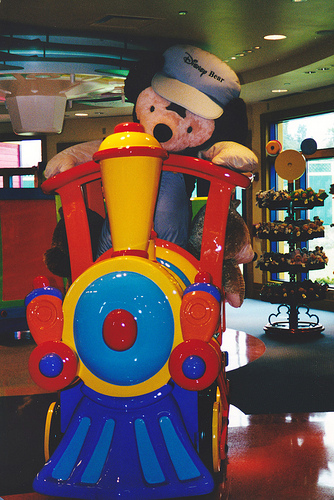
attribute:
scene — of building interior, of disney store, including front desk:
[1, 3, 333, 498]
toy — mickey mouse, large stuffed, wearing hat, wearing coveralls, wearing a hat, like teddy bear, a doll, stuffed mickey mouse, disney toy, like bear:
[43, 49, 249, 277]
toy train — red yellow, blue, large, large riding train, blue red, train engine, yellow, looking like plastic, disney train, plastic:
[26, 124, 246, 500]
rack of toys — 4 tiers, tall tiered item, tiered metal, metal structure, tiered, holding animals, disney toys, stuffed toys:
[252, 191, 333, 347]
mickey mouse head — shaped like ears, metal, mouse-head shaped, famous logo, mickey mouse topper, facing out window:
[265, 137, 318, 181]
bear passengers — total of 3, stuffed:
[37, 209, 251, 305]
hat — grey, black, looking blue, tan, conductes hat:
[156, 48, 245, 121]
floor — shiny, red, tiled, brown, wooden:
[234, 419, 328, 491]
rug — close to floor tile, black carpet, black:
[229, 360, 332, 416]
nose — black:
[253, 250, 258, 262]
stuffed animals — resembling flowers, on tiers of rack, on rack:
[256, 191, 327, 205]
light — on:
[266, 34, 288, 42]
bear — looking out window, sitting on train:
[190, 200, 252, 309]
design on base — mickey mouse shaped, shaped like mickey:
[266, 306, 320, 333]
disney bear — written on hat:
[181, 48, 230, 87]